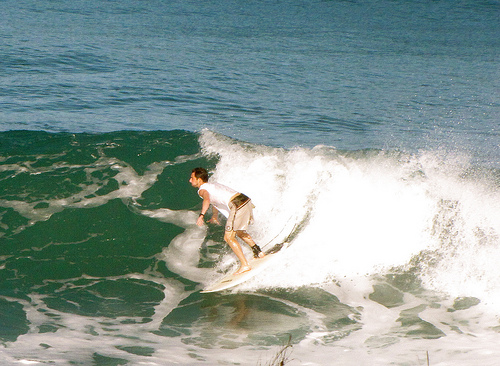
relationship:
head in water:
[191, 171, 203, 201] [0, 1, 500, 364]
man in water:
[189, 167, 266, 276] [0, 1, 500, 364]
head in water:
[189, 167, 209, 188] [0, 1, 500, 364]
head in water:
[189, 167, 209, 188] [225, 64, 412, 188]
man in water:
[189, 167, 266, 276] [225, 64, 412, 188]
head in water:
[189, 167, 209, 188] [257, 77, 344, 133]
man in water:
[189, 167, 266, 276] [257, 77, 344, 133]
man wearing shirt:
[189, 167, 266, 276] [197, 180, 239, 218]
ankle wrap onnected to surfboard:
[252, 243, 261, 253] [199, 243, 286, 293]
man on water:
[189, 167, 266, 276] [0, 1, 500, 364]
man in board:
[189, 167, 266, 276] [199, 237, 290, 293]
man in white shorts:
[189, 167, 266, 276] [218, 198, 259, 233]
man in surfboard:
[189, 167, 266, 276] [202, 247, 286, 301]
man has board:
[189, 172, 251, 244] [201, 247, 276, 289]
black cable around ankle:
[250, 243, 262, 256] [250, 241, 271, 254]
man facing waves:
[189, 167, 266, 276] [239, 142, 484, 357]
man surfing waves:
[189, 167, 266, 276] [116, 112, 483, 308]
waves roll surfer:
[204, 131, 464, 261] [196, 244, 298, 295]